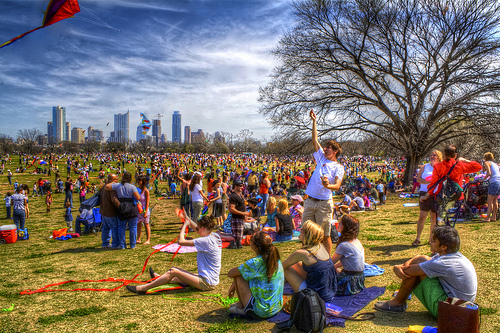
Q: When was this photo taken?
A: During the daytime.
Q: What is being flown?
A: A kite.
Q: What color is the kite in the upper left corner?
A: Red.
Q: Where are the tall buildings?
A: In the far distance.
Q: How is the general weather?
A: Sunny.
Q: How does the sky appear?
A: Mostly clear.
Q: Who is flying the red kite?
A: The guy in the white shirt.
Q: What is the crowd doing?
A: Watching kites.